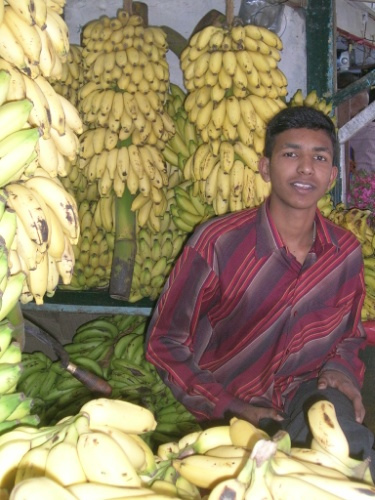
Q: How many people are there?
A: 1.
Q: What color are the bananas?
A: Yellow.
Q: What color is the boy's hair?
A: Black.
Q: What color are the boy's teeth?
A: White.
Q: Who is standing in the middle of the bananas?
A: Boy.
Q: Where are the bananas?
A: Around the boy.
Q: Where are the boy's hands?
A: On his legs.